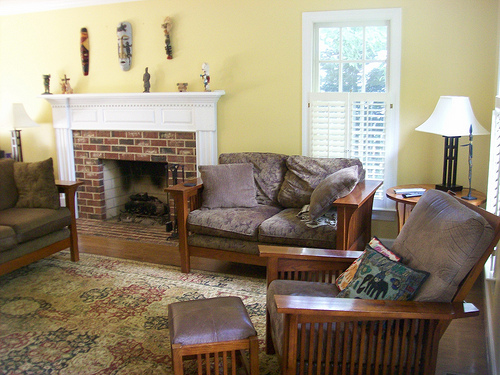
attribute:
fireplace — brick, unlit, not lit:
[72, 126, 162, 214]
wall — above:
[80, 21, 247, 106]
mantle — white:
[85, 90, 179, 148]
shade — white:
[399, 78, 493, 164]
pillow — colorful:
[345, 232, 425, 308]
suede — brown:
[212, 162, 264, 210]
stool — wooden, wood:
[163, 280, 242, 362]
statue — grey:
[99, 13, 131, 49]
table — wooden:
[390, 187, 432, 220]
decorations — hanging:
[69, 20, 136, 81]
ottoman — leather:
[172, 293, 232, 335]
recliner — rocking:
[301, 235, 492, 338]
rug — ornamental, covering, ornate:
[65, 281, 118, 342]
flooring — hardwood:
[99, 226, 161, 269]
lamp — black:
[395, 97, 467, 183]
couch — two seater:
[215, 155, 333, 222]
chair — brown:
[307, 212, 467, 351]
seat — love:
[236, 268, 423, 353]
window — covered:
[280, 56, 391, 148]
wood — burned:
[125, 178, 167, 208]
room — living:
[41, 37, 402, 349]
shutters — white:
[327, 100, 367, 143]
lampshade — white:
[423, 97, 476, 136]